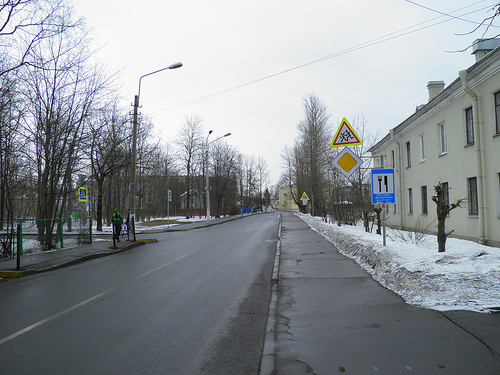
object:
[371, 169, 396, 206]
sign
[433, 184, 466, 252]
tree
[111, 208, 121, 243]
person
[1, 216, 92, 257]
fence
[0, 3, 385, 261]
trees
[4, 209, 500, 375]
street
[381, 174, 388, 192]
knife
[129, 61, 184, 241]
street lamp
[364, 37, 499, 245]
building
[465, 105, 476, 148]
window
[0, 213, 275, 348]
strip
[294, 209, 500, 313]
snow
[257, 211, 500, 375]
pavement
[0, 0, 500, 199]
sky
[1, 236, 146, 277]
sidewalk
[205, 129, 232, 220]
street lamp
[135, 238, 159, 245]
curb